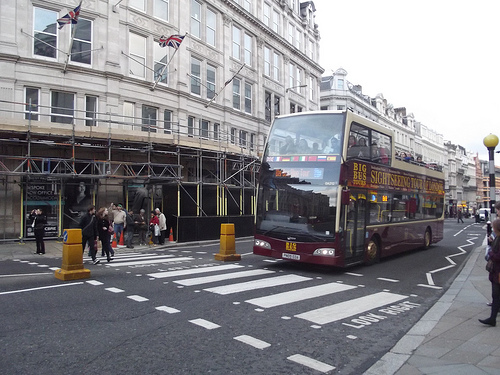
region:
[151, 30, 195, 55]
a flag hanging from the building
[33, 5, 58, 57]
a window on the building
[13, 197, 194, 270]
people standing next to the building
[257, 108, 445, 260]
a bus on the street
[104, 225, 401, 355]
the crosswalk on the street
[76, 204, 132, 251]
people who are crossing the street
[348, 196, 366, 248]
the door on the bus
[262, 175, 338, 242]
the windshield on the bus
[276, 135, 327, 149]
people sitting on the bus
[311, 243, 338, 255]
the headlight on the bus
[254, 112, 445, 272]
the bus is double decker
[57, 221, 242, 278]
yellow concrete dividers in road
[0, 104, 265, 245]
metal scaffolding on building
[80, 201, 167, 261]
large group of people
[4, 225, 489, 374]
white painted markings on road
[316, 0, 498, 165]
the sky is overcast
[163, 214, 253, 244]
black wall on subway stairs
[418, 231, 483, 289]
white zigzag line on street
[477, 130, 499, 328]
lamp post on sidewalk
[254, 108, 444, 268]
the bus is maroon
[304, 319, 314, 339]
edge of a road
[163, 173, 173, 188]
part of a building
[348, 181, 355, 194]
edge of a bus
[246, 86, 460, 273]
The bus is a doubledecker.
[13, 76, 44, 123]
The window is rectangular.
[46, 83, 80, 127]
The window is rectangular.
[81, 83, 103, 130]
The window is rectangular.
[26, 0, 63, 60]
The window is rectangular.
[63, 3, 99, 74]
The window is rectangular.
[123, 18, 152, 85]
The window is rectangular.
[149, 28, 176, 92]
The window is rectangular.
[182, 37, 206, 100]
The window is rectangular.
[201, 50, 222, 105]
The window is rectangular.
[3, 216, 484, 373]
white lines in road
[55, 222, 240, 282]
yellow concrete pillars in road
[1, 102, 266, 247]
metal awning on building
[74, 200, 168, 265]
people gathered in group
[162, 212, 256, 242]
black walls on subway stairs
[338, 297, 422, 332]
LOOK RIGHT painted on road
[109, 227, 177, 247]
orange safety cones on sidewalk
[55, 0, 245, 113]
flags mounted to building